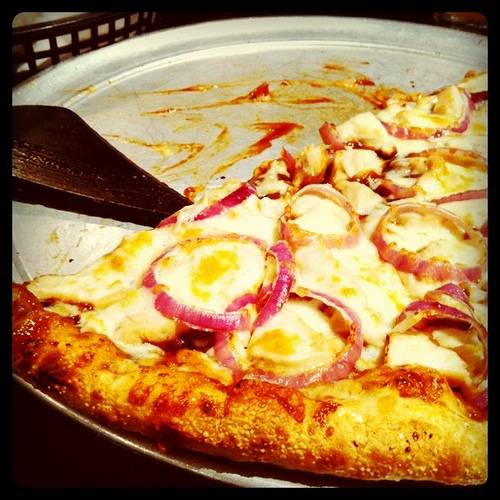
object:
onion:
[141, 233, 293, 330]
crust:
[12, 282, 489, 484]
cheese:
[13, 72, 489, 485]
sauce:
[63, 57, 441, 201]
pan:
[10, 16, 487, 490]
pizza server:
[11, 105, 194, 228]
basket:
[9, 1, 164, 86]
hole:
[96, 22, 110, 34]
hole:
[31, 39, 50, 51]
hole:
[128, 16, 138, 28]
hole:
[54, 33, 72, 48]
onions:
[144, 230, 361, 388]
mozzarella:
[12, 68, 489, 483]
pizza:
[10, 66, 487, 489]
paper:
[12, 9, 156, 72]